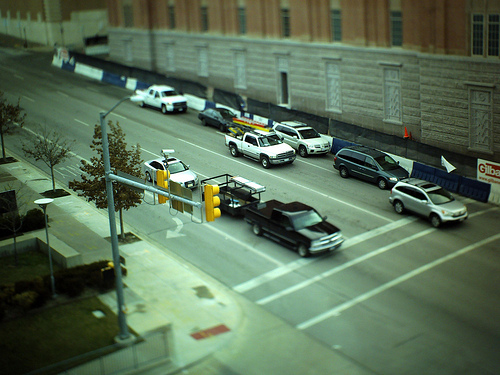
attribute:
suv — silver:
[452, 215, 464, 228]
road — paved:
[328, 224, 497, 375]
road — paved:
[377, 223, 496, 295]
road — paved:
[307, 231, 493, 364]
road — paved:
[216, 262, 400, 344]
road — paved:
[253, 306, 380, 375]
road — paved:
[269, 263, 377, 312]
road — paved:
[306, 284, 402, 375]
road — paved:
[359, 214, 402, 259]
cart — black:
[209, 154, 259, 212]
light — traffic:
[198, 179, 222, 222]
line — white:
[296, 230, 497, 329]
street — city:
[5, 29, 495, 372]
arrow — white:
[160, 211, 190, 246]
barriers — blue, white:
[65, 50, 498, 209]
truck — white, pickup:
[225, 128, 299, 168]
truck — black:
[242, 189, 347, 263]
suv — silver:
[386, 177, 469, 231]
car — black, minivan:
[331, 143, 412, 193]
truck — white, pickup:
[223, 122, 298, 171]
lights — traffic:
[203, 181, 222, 227]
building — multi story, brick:
[105, 7, 498, 166]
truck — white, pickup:
[133, 79, 194, 117]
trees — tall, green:
[65, 110, 149, 239]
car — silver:
[141, 152, 202, 201]